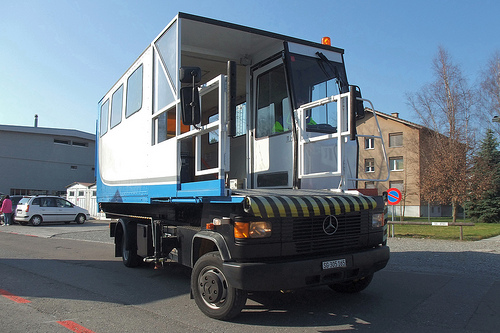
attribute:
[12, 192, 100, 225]
car — pink, white, parked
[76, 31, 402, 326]
truck — white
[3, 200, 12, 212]
coat — pink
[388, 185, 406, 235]
sign — red, blue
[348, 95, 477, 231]
building — brown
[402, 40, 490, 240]
tree — bare